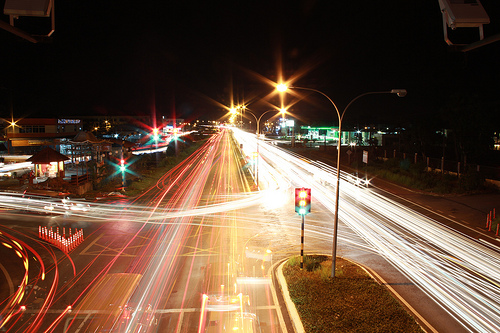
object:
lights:
[150, 195, 235, 229]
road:
[68, 135, 498, 333]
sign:
[358, 150, 370, 165]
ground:
[339, 159, 411, 196]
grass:
[305, 276, 366, 311]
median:
[273, 243, 433, 332]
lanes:
[184, 128, 246, 331]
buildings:
[262, 111, 293, 135]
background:
[0, 0, 500, 325]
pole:
[344, 146, 354, 166]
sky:
[5, 3, 499, 128]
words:
[55, 117, 84, 126]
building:
[4, 114, 106, 165]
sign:
[158, 118, 193, 141]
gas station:
[296, 118, 376, 151]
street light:
[252, 69, 309, 109]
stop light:
[292, 185, 315, 217]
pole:
[300, 214, 309, 269]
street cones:
[37, 224, 86, 253]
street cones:
[488, 210, 492, 232]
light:
[117, 165, 127, 170]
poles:
[287, 84, 342, 118]